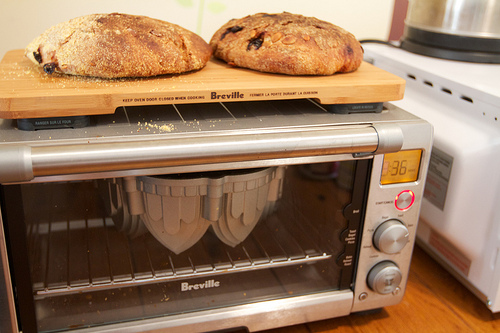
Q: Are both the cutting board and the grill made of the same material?
A: No, the cutting board is made of wood and the grill is made of metal.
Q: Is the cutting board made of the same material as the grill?
A: No, the cutting board is made of wood and the grill is made of metal.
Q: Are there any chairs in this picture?
A: No, there are no chairs.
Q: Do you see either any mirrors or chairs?
A: No, there are no chairs or mirrors.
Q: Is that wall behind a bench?
A: No, the wall is behind an appliance.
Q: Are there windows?
A: Yes, there is a window.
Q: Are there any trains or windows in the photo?
A: Yes, there is a window.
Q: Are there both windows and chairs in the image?
A: No, there is a window but no chairs.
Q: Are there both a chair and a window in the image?
A: No, there is a window but no chairs.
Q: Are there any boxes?
A: No, there are no boxes.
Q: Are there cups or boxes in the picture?
A: No, there are no boxes or cups.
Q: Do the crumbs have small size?
A: Yes, the crumbs are small.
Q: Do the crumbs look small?
A: Yes, the crumbs are small.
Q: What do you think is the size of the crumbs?
A: The crumbs are small.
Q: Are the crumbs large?
A: No, the crumbs are small.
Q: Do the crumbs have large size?
A: No, the crumbs are small.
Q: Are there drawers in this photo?
A: No, there are no drawers.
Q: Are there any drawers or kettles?
A: No, there are no drawers or kettles.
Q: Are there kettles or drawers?
A: No, there are no drawers or kettles.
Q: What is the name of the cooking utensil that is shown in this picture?
A: The cooking utensil is a cutting board.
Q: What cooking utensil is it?
A: The cooking utensil is a cutting board.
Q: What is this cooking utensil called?
A: This is a cutting board.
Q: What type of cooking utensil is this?
A: This is a cutting board.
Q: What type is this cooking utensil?
A: This is a cutting board.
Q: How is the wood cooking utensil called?
A: The cooking utensil is a cutting board.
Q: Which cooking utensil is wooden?
A: The cooking utensil is a cutting board.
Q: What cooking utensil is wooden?
A: The cooking utensil is a cutting board.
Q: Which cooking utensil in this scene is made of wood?
A: The cooking utensil is a cutting board.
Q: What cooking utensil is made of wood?
A: The cooking utensil is a cutting board.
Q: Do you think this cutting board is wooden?
A: Yes, the cutting board is wooden.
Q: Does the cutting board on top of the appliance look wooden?
A: Yes, the cutting board is wooden.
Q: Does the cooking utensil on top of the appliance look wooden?
A: Yes, the cutting board is wooden.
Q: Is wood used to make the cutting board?
A: Yes, the cutting board is made of wood.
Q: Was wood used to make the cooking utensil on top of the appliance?
A: Yes, the cutting board is made of wood.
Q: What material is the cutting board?
A: The cutting board is made of wood.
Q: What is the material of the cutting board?
A: The cutting board is made of wood.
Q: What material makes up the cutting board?
A: The cutting board is made of wood.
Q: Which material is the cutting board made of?
A: The cutting board is made of wood.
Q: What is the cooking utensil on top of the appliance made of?
A: The cutting board is made of wood.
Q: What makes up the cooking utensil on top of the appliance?
A: The cutting board is made of wood.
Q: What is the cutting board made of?
A: The cutting board is made of wood.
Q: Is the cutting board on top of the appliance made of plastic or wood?
A: The cutting board is made of wood.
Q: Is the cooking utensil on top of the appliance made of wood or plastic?
A: The cutting board is made of wood.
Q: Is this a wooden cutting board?
A: Yes, this is a wooden cutting board.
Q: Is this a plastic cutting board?
A: No, this is a wooden cutting board.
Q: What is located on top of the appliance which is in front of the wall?
A: The cutting board is on top of the appliance.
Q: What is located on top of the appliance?
A: The cutting board is on top of the appliance.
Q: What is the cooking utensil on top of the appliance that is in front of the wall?
A: The cooking utensil is a cutting board.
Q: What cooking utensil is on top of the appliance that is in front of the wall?
A: The cooking utensil is a cutting board.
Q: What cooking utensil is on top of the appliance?
A: The cooking utensil is a cutting board.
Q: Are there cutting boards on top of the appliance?
A: Yes, there is a cutting board on top of the appliance.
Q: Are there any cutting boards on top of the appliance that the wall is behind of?
A: Yes, there is a cutting board on top of the appliance.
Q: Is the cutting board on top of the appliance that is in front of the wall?
A: Yes, the cutting board is on top of the appliance.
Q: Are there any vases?
A: No, there are no vases.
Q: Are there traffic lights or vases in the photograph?
A: No, there are no vases or traffic lights.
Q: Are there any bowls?
A: No, there are no bowls.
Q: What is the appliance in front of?
A: The appliance is in front of the wall.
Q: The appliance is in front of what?
A: The appliance is in front of the wall.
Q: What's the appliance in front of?
A: The appliance is in front of the wall.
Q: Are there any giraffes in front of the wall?
A: No, there is an appliance in front of the wall.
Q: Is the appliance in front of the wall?
A: Yes, the appliance is in front of the wall.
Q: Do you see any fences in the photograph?
A: No, there are no fences.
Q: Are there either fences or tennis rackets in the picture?
A: No, there are no fences or tennis rackets.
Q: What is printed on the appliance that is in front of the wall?
A: The logo is printed on the appliance.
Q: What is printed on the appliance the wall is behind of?
A: The logo is printed on the appliance.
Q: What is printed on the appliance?
A: The logo is printed on the appliance.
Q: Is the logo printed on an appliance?
A: Yes, the logo is printed on an appliance.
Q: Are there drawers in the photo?
A: No, there are no drawers.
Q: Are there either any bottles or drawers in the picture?
A: No, there are no drawers or bottles.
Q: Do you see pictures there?
A: No, there are no pictures.